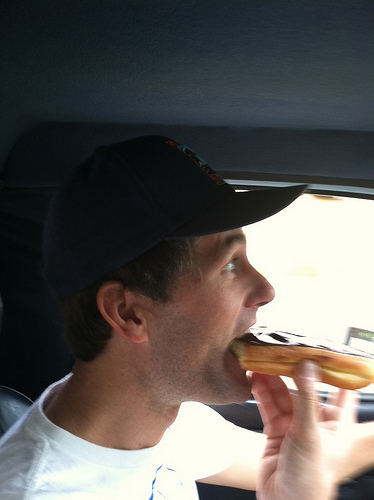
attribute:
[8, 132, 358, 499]
man — biting, driving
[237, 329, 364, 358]
icing — chocolate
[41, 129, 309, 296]
hat — black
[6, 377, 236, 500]
t-shirt — white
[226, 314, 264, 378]
mouth — taking a bite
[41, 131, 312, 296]
baseball cap — black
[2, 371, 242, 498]
tee shirt — white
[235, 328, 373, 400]
eclair — golden brown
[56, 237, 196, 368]
hair — short